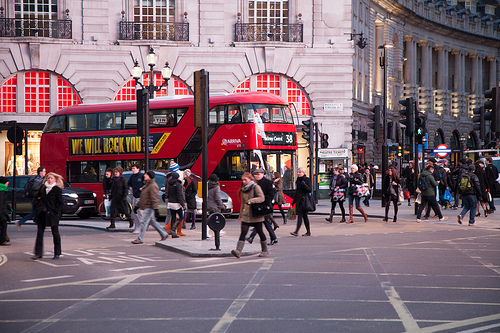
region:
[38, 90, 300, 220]
double decker bus on the street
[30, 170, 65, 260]
woman crossing the street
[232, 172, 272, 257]
girl wearing beige boots and jacket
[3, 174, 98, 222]
black car next to double decker bus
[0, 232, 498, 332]
white lines on the street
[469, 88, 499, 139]
traffic lights hanging from posts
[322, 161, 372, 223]
two people walking on the street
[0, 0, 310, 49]
three balconies on the building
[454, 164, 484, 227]
mancarrying a backpack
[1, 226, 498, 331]
a pedestrian cross walk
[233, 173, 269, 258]
a pedestrian in street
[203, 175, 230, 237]
a pedestrian in street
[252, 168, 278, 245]
a pedestrian in street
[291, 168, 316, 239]
a pedestrian in street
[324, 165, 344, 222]
a pedestrian in street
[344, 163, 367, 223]
a pedestrian in street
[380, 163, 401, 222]
a pedestrian in street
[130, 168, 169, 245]
a pedestrian in street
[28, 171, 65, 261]
a pedestrian in street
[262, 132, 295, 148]
The marquee display on the bus.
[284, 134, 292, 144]
The number 38 on the bus.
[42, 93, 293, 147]
The top level of the bus.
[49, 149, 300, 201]
The bottom level of the bus.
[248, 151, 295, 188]
The front window on the lower level of the bus.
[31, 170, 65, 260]
The lady in the street wearing the beige turtleneck.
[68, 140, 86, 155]
The word We on the bus.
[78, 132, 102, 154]
The word Will on the bus.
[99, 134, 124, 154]
The word ROCK on the bus.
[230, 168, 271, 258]
woman walking across the crosswalk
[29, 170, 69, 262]
woman walking across the crosswalk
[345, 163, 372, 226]
woman walking across the crosswalk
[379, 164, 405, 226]
woman walking across the crosswalk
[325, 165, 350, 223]
woman walking across the crosswalk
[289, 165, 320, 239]
woman walking across the crosswalk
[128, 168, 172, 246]
man walking across the crosswalk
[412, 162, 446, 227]
man walking across the crosswalk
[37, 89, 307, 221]
red double decker bus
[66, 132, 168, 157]
sign that says "we will rock you"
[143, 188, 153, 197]
man wearing brown jacket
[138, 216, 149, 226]
man wearing blue jeans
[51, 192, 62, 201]
woman wearing black jacket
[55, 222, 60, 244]
woman wearing black pants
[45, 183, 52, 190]
woman wearing white scarf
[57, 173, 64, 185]
woman with blonde hair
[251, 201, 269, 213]
woman with black purse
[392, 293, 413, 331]
white stripe in street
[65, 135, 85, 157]
word we on bus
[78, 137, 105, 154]
word will on bus